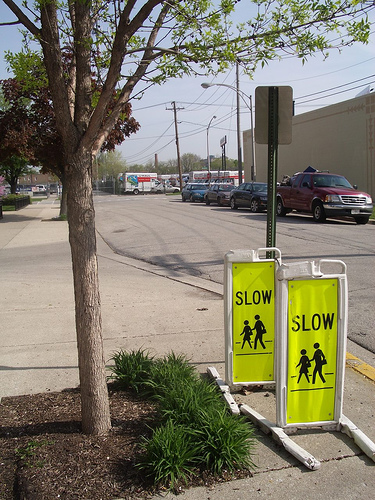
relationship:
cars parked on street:
[273, 169, 373, 225] [92, 192, 369, 259]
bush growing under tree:
[159, 383, 232, 421] [2, 0, 231, 443]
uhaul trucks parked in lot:
[109, 160, 247, 199] [93, 162, 248, 196]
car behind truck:
[228, 177, 270, 211] [276, 167, 370, 223]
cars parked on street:
[273, 169, 373, 225] [92, 191, 372, 357]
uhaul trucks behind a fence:
[109, 160, 247, 199] [94, 173, 186, 198]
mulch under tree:
[1, 374, 207, 498] [0, 0, 163, 439]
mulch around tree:
[1, 374, 207, 498] [0, 0, 373, 435]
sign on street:
[223, 244, 284, 391] [82, 184, 374, 367]